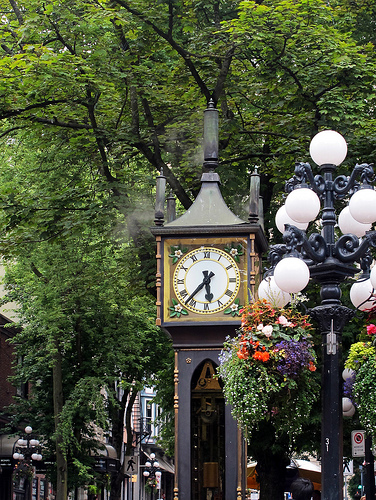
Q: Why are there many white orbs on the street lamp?
A: Lots of light.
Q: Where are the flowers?
A: Hanging basket.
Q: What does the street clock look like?
A: Grandfather clock.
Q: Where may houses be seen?
A: Other side street.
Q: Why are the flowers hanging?
A: Visible pedestrians.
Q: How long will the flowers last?
A: Short visibility.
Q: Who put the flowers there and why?
A: City worker share beauty.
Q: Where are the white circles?
A: On the lamp posts.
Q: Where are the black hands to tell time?
A: On the clock.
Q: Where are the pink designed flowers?
A: On the clock.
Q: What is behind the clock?
A: Trees.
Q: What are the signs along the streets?
A: Street signs.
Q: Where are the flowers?
A: Near the lamp post.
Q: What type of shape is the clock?
A: Circle.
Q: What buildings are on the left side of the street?
A: Businesses.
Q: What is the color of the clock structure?
A: Black.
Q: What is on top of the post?
A: A clock.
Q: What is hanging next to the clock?
A: A plant.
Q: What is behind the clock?
A: Lots of trees.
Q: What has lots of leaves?
A: The trees.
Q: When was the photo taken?
A: During the daytime.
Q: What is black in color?
A: The street lamp.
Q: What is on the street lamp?
A: Lights.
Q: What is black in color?
A: The pole.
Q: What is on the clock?
A: Hands.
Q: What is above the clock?
A: The tree.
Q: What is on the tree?
A: Leaves.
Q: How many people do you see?
A: None.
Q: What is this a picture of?
A: A clock.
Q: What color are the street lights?
A: Black and white.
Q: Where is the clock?
A: In the street.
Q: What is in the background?
A: A tree.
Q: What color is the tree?
A: Green.